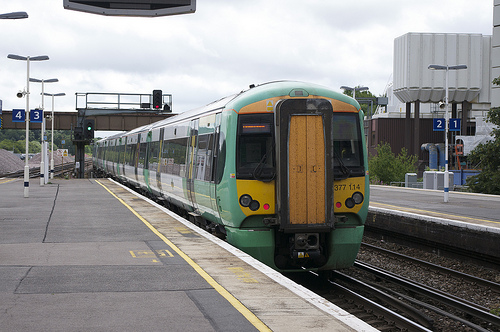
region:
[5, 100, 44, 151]
White number 4 in blue sign.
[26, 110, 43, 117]
White number 3 in blue sign.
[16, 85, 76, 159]
Blue signs attached to light posts.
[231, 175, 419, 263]
Lights on back of train.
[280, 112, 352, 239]
Wood door on back of train.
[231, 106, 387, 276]
Yellow area on back of train.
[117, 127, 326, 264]
Train is mostly green.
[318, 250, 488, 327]
Train is on train tracks.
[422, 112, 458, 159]
White number 2 on blue sign.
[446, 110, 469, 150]
White 1 on blue sign.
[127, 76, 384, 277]
commuter train on track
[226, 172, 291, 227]
yellow on front of train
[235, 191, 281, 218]
lights on front of train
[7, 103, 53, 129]
white numbers on blue sign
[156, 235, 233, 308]
yellow line on platform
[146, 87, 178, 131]
glowing red light over train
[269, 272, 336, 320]
white edge of platform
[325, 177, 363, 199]
numbers on front of train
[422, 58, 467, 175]
light on white pole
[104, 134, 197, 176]
windows on side of train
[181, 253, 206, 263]
yellow stripe on the ground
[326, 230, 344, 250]
part of a train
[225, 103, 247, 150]
edge of a train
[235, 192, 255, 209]
lights of a train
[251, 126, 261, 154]
window of a train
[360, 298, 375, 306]
part of a railway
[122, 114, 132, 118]
part of a bridge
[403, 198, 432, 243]
edge of the rail way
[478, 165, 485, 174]
leaves of a tree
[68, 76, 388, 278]
A long green train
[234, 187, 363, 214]
Headlights on a train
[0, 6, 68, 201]
A row of lightpoles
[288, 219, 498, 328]
A section of train tracks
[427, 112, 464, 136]
Numbered signs on a light pole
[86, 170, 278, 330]
A yellow stripe on the concrete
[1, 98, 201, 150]
A section of a bridge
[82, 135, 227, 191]
Windows on the train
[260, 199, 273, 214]
A red light on the train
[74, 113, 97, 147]
A green traffic signal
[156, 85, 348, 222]
this is a train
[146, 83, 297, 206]
the train is long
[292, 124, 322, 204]
the front is yellow in color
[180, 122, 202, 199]
the door is closed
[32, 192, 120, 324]
this is a pavement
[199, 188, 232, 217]
the train is green in color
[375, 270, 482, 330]
these are the rails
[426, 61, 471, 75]
this is a street light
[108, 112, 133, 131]
this is a bridge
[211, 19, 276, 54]
the cloud is white in color